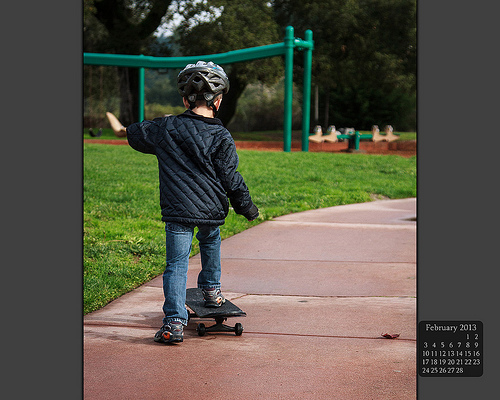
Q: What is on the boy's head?
A: A helmet.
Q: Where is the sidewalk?
A: By the grass.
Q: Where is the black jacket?
A: On the boy.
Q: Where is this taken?
A: In a park.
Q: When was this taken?
A: During spring.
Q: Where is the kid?
A: On the skateboard.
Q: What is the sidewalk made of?
A: Pavement.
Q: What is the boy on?
A: A skateboard.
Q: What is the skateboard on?
A: The pavement.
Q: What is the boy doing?
A: Skateboarding.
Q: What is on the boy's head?
A: A helmet.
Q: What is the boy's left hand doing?
A: The hand is raised in the air for balance.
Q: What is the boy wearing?
A: A coat.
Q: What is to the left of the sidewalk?
A: The grassy lawn.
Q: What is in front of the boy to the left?
A: A small park.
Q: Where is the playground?
A: To the front left of the boy.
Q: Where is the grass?
A: To the left of the sidewalk.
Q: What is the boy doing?
A: Skateboarding.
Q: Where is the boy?
A: On a sidewalk.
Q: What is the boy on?
A: A skateboard.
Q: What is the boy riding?
A: Skateboard.